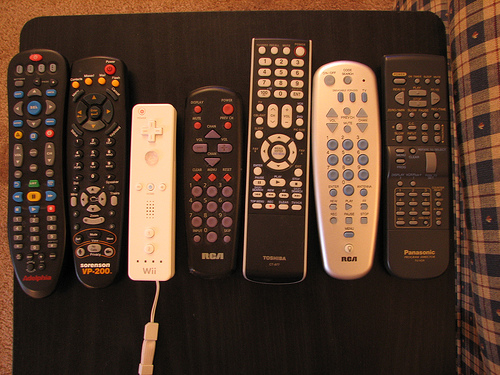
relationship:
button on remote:
[392, 188, 409, 198] [381, 52, 451, 279]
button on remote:
[434, 190, 444, 197] [379, 42, 453, 284]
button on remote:
[356, 136, 371, 149] [305, 55, 381, 281]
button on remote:
[326, 139, 340, 153] [184, 80, 236, 278]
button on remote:
[356, 167, 370, 182] [68, 52, 121, 286]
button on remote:
[323, 166, 338, 182] [236, 38, 316, 289]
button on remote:
[326, 139, 340, 153] [305, 55, 381, 281]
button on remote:
[319, 130, 347, 161] [305, 55, 381, 281]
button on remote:
[322, 106, 341, 133] [305, 55, 381, 281]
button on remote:
[266, 103, 279, 130] [236, 38, 316, 289]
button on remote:
[288, 65, 313, 77] [156, 71, 324, 316]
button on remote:
[190, 185, 202, 198] [179, 82, 244, 281]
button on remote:
[190, 199, 203, 212] [179, 82, 244, 281]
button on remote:
[191, 215, 202, 228] [179, 82, 244, 281]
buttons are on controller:
[219, 36, 391, 326] [244, 29, 319, 283]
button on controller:
[355, 137, 369, 155] [4, 47, 70, 301]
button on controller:
[424, 148, 437, 174] [244, 29, 319, 283]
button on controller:
[83, 184, 105, 199] [178, 83, 242, 283]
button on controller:
[86, 246, 103, 259] [125, 100, 177, 285]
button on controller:
[260, 103, 279, 130] [65, 48, 133, 296]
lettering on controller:
[18, 273, 53, 280] [4, 47, 70, 301]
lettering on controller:
[132, 255, 167, 300] [125, 100, 177, 285]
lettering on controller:
[201, 250, 222, 260] [178, 83, 242, 283]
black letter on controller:
[340, 256, 346, 263] [310, 63, 380, 279]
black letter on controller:
[347, 257, 352, 261] [310, 63, 380, 279]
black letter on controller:
[352, 256, 358, 261] [310, 63, 380, 279]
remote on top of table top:
[379, 42, 453, 284] [11, 12, 458, 373]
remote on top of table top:
[305, 55, 381, 281] [11, 12, 458, 373]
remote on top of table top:
[131, 104, 177, 283] [11, 12, 458, 373]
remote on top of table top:
[186, 82, 244, 284] [11, 12, 458, 373]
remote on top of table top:
[236, 38, 316, 289] [11, 12, 458, 373]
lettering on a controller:
[401, 248, 436, 257] [378, 52, 453, 284]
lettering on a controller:
[262, 251, 285, 261] [310, 63, 380, 279]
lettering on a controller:
[201, 250, 222, 260] [244, 29, 319, 283]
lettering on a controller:
[28, 55, 40, 61] [125, 104, 177, 285]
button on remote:
[424, 148, 437, 174] [381, 52, 451, 279]